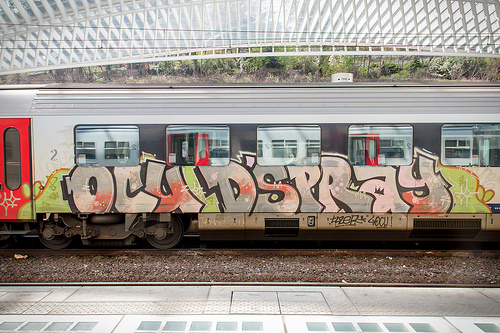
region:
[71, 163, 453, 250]
a graffiti on the train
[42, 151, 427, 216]
a graffiti on the train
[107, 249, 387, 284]
the train track is brown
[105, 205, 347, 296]
the train track is brown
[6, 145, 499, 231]
Art work on the side of a train.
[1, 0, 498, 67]
A silver fence is illuminated.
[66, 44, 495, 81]
Grass and bushes behind an opening.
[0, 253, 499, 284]
The ground is covered with gravel.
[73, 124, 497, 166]
Five windows next to each other.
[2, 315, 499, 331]
Fifteen square shadows with three vertical lines.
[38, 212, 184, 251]
A pair of train wheels.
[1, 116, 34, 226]
A red door with an oval window.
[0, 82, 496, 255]
A train car is on the tracks.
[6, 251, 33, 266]
small white stone on the platform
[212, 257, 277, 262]
gray gravel on the platform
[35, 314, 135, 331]
section of blue squares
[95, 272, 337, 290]
solid black lines on the ground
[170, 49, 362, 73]
green trees in the background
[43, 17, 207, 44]
small square lines in the ceiling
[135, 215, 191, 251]
small black wheels on train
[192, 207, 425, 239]
long silver bracket on bottom of train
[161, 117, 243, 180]
large window in train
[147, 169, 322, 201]
graffiti on the side of the train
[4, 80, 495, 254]
long metal train car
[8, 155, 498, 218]
graffiti on side of train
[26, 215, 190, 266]
brown wheels on side of train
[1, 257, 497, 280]
line of grey gravel on side of train tracks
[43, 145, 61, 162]
grey number on side of train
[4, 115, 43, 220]
red door on side of train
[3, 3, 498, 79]
glass and metal overpass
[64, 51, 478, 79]
trees and foliage beyond train station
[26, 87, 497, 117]
ridged grey lines on roof of train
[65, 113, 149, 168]
window on side of train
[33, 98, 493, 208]
car on a train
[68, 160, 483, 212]
graffiti on the train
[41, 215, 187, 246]
wheels on the train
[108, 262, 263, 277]
dirt and gravel beneath track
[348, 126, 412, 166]
window on the train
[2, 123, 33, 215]
door on the train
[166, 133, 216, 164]
open door on train next to train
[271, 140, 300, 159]
window on train next to train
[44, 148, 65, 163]
number on the train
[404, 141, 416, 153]
number on train next to train